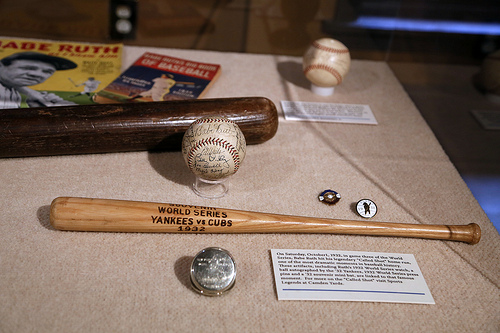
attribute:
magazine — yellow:
[3, 35, 123, 106]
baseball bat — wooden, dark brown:
[2, 99, 278, 160]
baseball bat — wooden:
[47, 193, 480, 250]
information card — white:
[279, 96, 374, 126]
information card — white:
[268, 246, 441, 310]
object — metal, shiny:
[192, 249, 234, 292]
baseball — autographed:
[305, 39, 351, 87]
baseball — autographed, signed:
[181, 114, 247, 179]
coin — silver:
[189, 243, 235, 293]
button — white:
[354, 200, 375, 218]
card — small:
[267, 249, 436, 306]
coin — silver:
[189, 248, 232, 291]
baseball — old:
[177, 122, 250, 172]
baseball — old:
[287, 25, 352, 91]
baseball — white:
[179, 118, 252, 178]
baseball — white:
[297, 34, 357, 76]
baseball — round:
[159, 108, 249, 175]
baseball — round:
[287, 33, 371, 95]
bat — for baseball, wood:
[40, 188, 484, 249]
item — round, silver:
[191, 250, 242, 310]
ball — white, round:
[305, 48, 355, 97]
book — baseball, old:
[107, 44, 186, 101]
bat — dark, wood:
[12, 104, 299, 144]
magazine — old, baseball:
[3, 36, 96, 100]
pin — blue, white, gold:
[318, 177, 343, 209]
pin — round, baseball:
[354, 199, 394, 219]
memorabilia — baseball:
[30, 44, 370, 296]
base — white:
[310, 79, 336, 99]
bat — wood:
[34, 173, 496, 269]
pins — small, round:
[317, 173, 391, 225]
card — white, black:
[260, 245, 432, 305]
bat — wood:
[34, 90, 304, 140]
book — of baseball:
[2, 37, 124, 112]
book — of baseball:
[108, 50, 214, 98]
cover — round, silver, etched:
[188, 244, 239, 295]